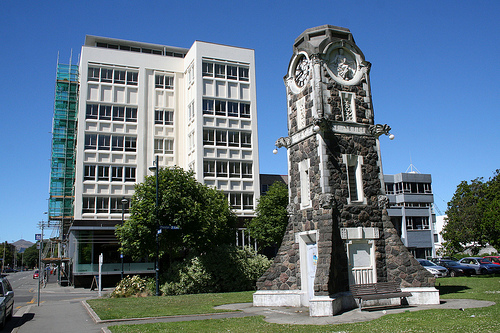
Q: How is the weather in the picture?
A: It is clear.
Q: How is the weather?
A: It is clear.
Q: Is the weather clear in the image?
A: Yes, it is clear.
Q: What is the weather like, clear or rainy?
A: It is clear.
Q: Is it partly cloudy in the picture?
A: No, it is clear.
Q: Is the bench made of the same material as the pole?
A: No, the bench is made of wood and the pole is made of metal.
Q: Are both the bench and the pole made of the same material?
A: No, the bench is made of wood and the pole is made of metal.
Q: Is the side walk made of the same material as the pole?
A: No, the side walk is made of cement and the pole is made of metal.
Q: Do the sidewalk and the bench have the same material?
A: No, the sidewalk is made of cement and the bench is made of wood.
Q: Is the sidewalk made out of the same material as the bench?
A: No, the sidewalk is made of cement and the bench is made of wood.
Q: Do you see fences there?
A: No, there are no fences.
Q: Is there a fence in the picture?
A: No, there are no fences.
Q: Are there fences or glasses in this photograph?
A: No, there are no fences or glasses.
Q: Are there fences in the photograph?
A: No, there are no fences.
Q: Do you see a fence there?
A: No, there are no fences.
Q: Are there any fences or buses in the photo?
A: No, there are no fences or buses.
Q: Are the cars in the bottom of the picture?
A: Yes, the cars are in the bottom of the image.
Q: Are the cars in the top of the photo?
A: No, the cars are in the bottom of the image.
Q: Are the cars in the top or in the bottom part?
A: The cars are in the bottom of the image.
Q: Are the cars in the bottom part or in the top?
A: The cars are in the bottom of the image.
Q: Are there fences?
A: No, there are no fences.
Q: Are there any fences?
A: No, there are no fences.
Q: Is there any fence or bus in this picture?
A: No, there are no fences or buses.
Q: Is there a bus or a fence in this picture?
A: No, there are no fences or buses.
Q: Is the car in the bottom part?
A: Yes, the car is in the bottom of the image.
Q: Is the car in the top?
A: No, the car is in the bottom of the image.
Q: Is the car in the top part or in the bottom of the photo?
A: The car is in the bottom of the image.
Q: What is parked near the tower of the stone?
A: The car is parked near the tower.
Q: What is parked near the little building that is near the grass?
A: The car is parked near the tower.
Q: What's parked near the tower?
A: The car is parked near the tower.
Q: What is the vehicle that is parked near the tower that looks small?
A: The vehicle is a car.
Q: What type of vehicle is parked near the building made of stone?
A: The vehicle is a car.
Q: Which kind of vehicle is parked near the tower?
A: The vehicle is a car.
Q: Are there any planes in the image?
A: No, there are no planes.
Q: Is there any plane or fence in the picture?
A: No, there are no airplanes or fences.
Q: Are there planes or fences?
A: No, there are no planes or fences.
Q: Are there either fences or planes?
A: No, there are no planes or fences.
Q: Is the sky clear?
A: Yes, the sky is clear.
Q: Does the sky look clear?
A: Yes, the sky is clear.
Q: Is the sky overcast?
A: No, the sky is clear.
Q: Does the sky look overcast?
A: No, the sky is clear.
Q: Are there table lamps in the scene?
A: No, there are no table lamps.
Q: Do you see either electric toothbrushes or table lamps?
A: No, there are no table lamps or electric toothbrushes.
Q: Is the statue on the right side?
A: Yes, the statue is on the right of the image.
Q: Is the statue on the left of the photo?
A: No, the statue is on the right of the image.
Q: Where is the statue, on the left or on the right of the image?
A: The statue is on the right of the image.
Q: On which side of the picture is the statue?
A: The statue is on the right of the image.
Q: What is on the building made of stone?
A: The statue is on the tower.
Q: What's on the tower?
A: The statue is on the tower.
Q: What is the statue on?
A: The statue is on the tower.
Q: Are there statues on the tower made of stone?
A: Yes, there is a statue on the tower.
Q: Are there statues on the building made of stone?
A: Yes, there is a statue on the tower.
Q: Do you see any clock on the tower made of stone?
A: No, there is a statue on the tower.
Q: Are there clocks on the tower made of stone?
A: No, there is a statue on the tower.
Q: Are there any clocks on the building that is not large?
A: No, there is a statue on the tower.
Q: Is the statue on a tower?
A: Yes, the statue is on a tower.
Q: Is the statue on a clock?
A: No, the statue is on a tower.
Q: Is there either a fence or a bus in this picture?
A: No, there are no fences or buses.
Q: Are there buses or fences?
A: No, there are no fences or buses.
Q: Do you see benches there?
A: Yes, there is a bench.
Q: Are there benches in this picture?
A: Yes, there is a bench.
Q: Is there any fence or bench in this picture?
A: Yes, there is a bench.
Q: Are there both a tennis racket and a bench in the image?
A: No, there is a bench but no rackets.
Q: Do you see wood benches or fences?
A: Yes, there is a wood bench.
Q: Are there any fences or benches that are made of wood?
A: Yes, the bench is made of wood.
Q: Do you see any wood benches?
A: Yes, there is a wood bench.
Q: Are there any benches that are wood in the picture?
A: Yes, there is a wood bench.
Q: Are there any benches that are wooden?
A: Yes, there is a bench that is wooden.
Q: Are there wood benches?
A: Yes, there is a bench that is made of wood.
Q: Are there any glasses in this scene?
A: No, there are no glasses.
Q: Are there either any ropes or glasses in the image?
A: No, there are no glasses or ropes.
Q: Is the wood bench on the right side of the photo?
A: Yes, the bench is on the right of the image.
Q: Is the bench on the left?
A: No, the bench is on the right of the image.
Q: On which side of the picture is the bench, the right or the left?
A: The bench is on the right of the image.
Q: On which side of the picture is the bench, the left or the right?
A: The bench is on the right of the image.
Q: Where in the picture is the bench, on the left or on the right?
A: The bench is on the right of the image.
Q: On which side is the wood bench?
A: The bench is on the right of the image.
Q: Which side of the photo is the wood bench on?
A: The bench is on the right of the image.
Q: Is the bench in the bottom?
A: Yes, the bench is in the bottom of the image.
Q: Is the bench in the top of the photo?
A: No, the bench is in the bottom of the image.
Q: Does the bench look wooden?
A: Yes, the bench is wooden.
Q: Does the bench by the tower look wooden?
A: Yes, the bench is wooden.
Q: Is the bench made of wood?
A: Yes, the bench is made of wood.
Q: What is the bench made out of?
A: The bench is made of wood.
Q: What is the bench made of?
A: The bench is made of wood.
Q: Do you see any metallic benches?
A: No, there is a bench but it is wooden.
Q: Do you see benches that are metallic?
A: No, there is a bench but it is wooden.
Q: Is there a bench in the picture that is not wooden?
A: No, there is a bench but it is wooden.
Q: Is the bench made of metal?
A: No, the bench is made of wood.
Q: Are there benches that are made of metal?
A: No, there is a bench but it is made of wood.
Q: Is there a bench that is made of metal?
A: No, there is a bench but it is made of wood.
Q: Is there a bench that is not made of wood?
A: No, there is a bench but it is made of wood.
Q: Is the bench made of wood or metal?
A: The bench is made of wood.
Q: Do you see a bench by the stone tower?
A: Yes, there is a bench by the tower.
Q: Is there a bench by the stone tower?
A: Yes, there is a bench by the tower.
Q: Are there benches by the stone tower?
A: Yes, there is a bench by the tower.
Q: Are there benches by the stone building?
A: Yes, there is a bench by the tower.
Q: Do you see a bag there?
A: No, there are no bags.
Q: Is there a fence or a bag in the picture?
A: No, there are no bags or fences.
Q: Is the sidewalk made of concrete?
A: Yes, the sidewalk is made of concrete.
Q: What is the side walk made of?
A: The side walk is made of concrete.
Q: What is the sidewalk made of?
A: The side walk is made of concrete.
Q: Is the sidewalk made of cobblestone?
A: No, the sidewalk is made of cement.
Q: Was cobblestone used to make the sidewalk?
A: No, the sidewalk is made of cement.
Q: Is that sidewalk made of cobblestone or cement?
A: The sidewalk is made of cement.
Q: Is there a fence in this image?
A: No, there are no fences.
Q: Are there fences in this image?
A: No, there are no fences.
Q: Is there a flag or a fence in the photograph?
A: No, there are no fences or flags.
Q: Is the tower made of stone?
A: Yes, the tower is made of stone.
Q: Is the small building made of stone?
A: Yes, the tower is made of stone.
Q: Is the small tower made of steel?
A: No, the tower is made of stone.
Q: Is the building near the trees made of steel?
A: No, the tower is made of stone.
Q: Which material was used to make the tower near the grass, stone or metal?
A: The tower is made of stone.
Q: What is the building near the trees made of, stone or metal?
A: The tower is made of stone.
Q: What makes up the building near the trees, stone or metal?
A: The tower is made of stone.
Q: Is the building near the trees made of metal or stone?
A: The tower is made of stone.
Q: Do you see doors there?
A: Yes, there is a door.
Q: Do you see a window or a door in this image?
A: Yes, there is a door.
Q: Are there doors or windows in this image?
A: Yes, there is a door.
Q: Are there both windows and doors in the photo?
A: Yes, there are both a door and a window.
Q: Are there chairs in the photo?
A: No, there are no chairs.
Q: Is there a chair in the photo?
A: No, there are no chairs.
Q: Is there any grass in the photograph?
A: Yes, there is grass.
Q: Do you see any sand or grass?
A: Yes, there is grass.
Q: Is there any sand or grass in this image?
A: Yes, there is grass.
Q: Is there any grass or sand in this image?
A: Yes, there is grass.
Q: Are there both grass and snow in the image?
A: No, there is grass but no snow.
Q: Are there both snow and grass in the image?
A: No, there is grass but no snow.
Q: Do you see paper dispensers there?
A: No, there are no paper dispensers.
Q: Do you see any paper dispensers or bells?
A: No, there are no paper dispensers or bells.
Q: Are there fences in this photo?
A: No, there are no fences.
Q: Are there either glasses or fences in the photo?
A: No, there are no fences or glasses.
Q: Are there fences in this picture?
A: No, there are no fences.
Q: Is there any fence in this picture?
A: No, there are no fences.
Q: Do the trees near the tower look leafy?
A: Yes, the trees are leafy.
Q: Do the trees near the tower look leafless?
A: No, the trees are leafy.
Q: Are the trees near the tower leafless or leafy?
A: The trees are leafy.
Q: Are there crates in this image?
A: No, there are no crates.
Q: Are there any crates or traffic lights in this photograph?
A: No, there are no crates or traffic lights.